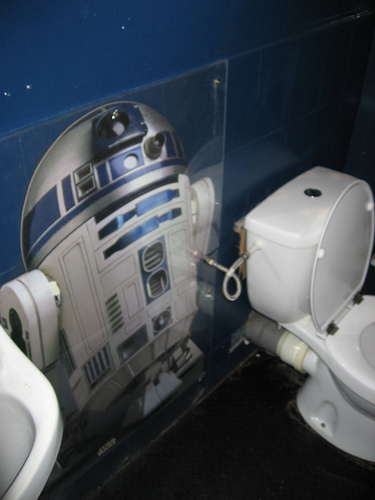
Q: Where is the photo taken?
A: Bathroom.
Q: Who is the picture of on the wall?
A: R2D2.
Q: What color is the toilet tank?
A: White.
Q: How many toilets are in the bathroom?
A: One.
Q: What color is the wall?
A: Blue.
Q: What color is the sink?
A: White.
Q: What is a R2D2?
A: A robot.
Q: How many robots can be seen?
A: One.